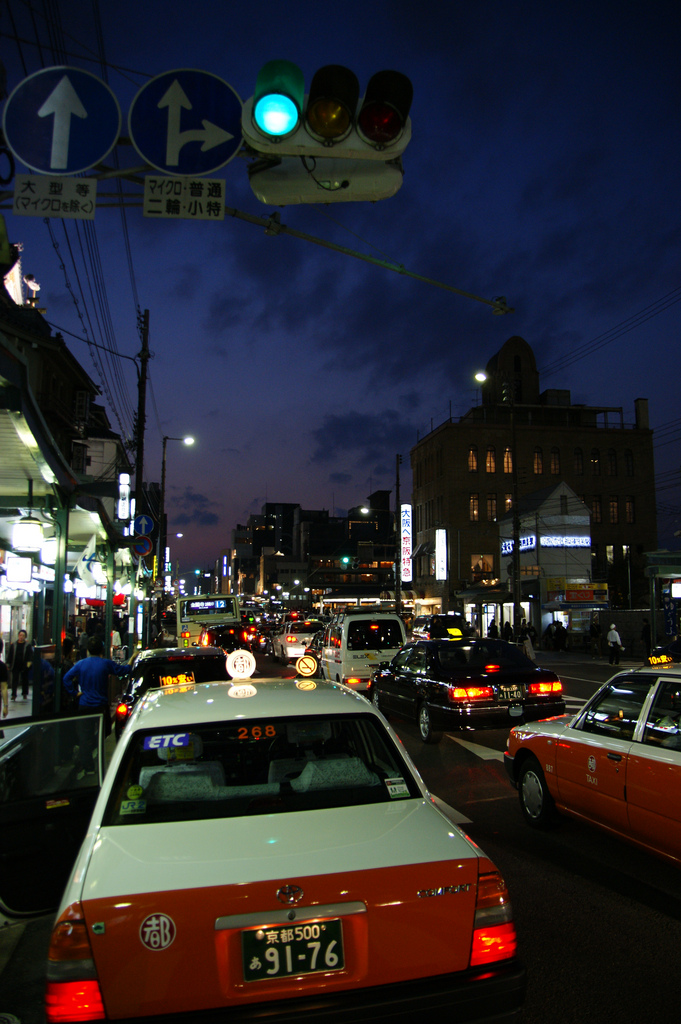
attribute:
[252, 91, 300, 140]
light — green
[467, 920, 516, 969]
tail light — red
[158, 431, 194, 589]
street light — tall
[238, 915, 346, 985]
license plate — black, white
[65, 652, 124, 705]
top — blue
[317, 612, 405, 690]
van — white, small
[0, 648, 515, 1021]
car — white, red